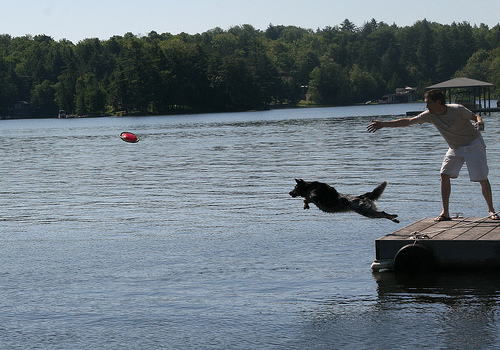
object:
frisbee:
[119, 130, 139, 144]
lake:
[0, 99, 498, 350]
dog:
[288, 178, 401, 224]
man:
[366, 89, 499, 222]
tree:
[271, 75, 287, 105]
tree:
[108, 68, 132, 114]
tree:
[339, 18, 355, 33]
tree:
[73, 76, 87, 120]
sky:
[0, 1, 498, 46]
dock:
[371, 216, 499, 272]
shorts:
[438, 135, 490, 183]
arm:
[366, 111, 428, 138]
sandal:
[434, 219, 450, 223]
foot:
[433, 209, 451, 222]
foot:
[488, 210, 499, 220]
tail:
[363, 180, 387, 201]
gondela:
[429, 78, 493, 109]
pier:
[470, 106, 499, 114]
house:
[381, 86, 420, 105]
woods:
[1, 18, 499, 121]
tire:
[393, 243, 436, 278]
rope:
[410, 212, 499, 239]